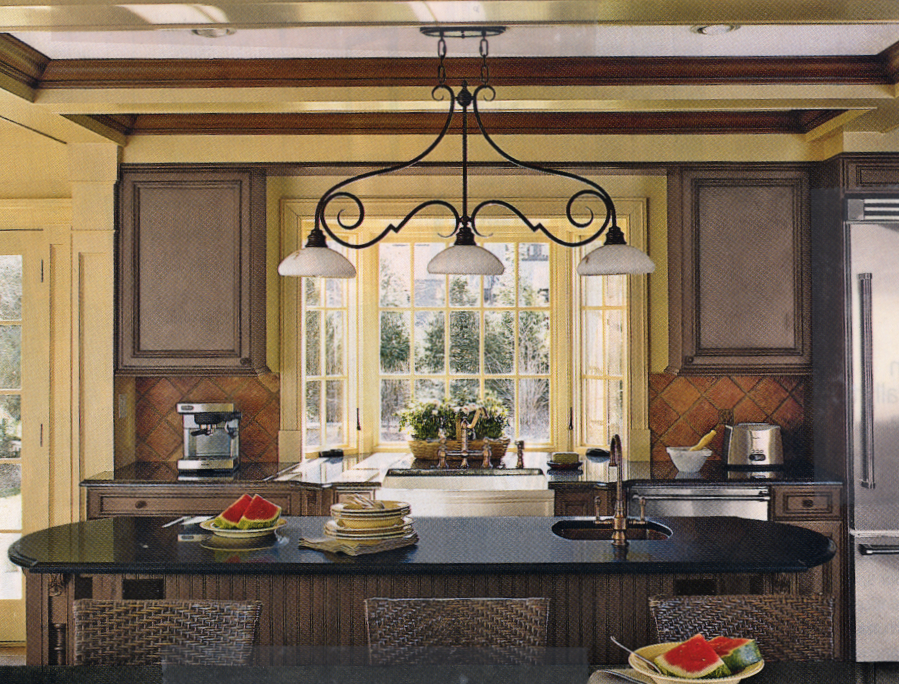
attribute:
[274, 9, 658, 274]
light — overhead, island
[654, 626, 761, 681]
watermelon — wedges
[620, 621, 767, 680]
bowl — yellow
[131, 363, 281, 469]
backsplash — orange-tiled, red-tiled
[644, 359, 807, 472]
backsplash — orange-tiled, red-tiled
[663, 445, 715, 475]
bowl — small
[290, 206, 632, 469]
window — large